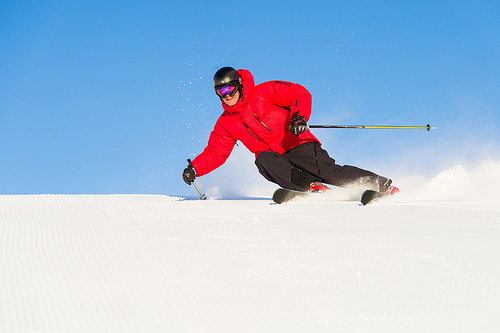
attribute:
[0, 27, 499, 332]
snow — white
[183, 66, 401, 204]
man — skiing, leaning, moving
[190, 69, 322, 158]
sweatshirt — red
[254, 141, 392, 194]
pants — black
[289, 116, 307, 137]
glove — black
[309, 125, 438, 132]
pole — black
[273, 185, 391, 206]
skis — black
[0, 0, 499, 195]
sky — blue